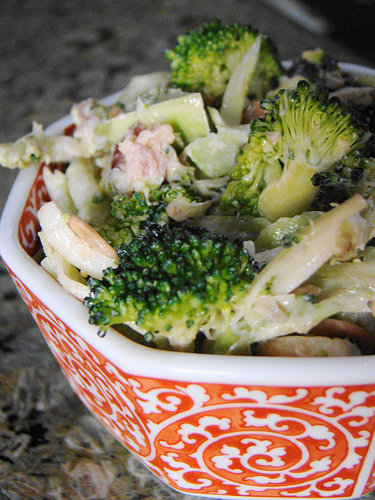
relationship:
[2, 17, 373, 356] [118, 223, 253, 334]
salad made with broccoli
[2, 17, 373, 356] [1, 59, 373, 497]
salad in bowl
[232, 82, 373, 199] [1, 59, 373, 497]
broccoli in bowl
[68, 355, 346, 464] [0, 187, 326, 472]
design on bowl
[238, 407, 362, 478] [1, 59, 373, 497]
design on bowl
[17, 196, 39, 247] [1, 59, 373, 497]
design on bowl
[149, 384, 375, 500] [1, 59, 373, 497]
design on bowl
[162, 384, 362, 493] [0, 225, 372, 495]
design on bowl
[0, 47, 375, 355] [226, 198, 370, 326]
sauce on pasta